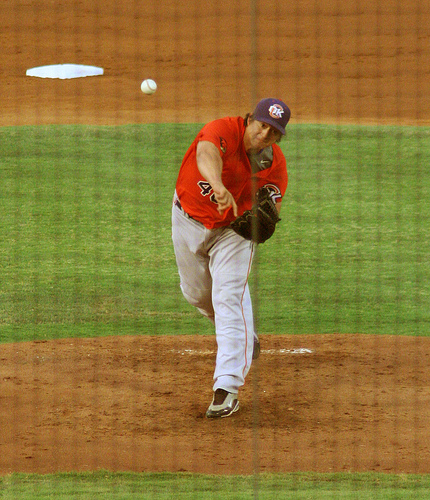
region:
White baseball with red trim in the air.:
[133, 70, 163, 101]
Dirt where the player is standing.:
[1, 340, 428, 474]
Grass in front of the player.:
[3, 471, 426, 498]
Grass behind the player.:
[1, 127, 429, 329]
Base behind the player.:
[25, 60, 106, 84]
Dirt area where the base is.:
[2, 1, 427, 120]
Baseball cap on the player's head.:
[249, 94, 296, 137]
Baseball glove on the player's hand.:
[230, 184, 283, 246]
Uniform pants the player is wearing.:
[162, 202, 270, 398]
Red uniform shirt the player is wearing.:
[163, 103, 306, 232]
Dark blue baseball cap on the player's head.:
[261, 89, 292, 128]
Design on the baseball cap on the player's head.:
[265, 99, 285, 118]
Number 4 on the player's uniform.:
[194, 176, 214, 194]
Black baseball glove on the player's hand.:
[236, 186, 283, 249]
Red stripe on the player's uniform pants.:
[243, 237, 253, 385]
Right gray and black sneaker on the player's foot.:
[206, 375, 242, 419]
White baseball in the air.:
[132, 73, 162, 96]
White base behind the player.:
[23, 46, 110, 85]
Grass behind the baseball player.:
[2, 125, 428, 329]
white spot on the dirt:
[268, 391, 306, 416]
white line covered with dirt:
[122, 331, 210, 362]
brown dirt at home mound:
[26, 311, 194, 452]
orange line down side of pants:
[226, 290, 272, 400]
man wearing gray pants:
[116, 190, 289, 418]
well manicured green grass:
[10, 157, 116, 289]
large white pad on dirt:
[6, 46, 113, 108]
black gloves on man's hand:
[204, 187, 296, 258]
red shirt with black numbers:
[146, 127, 313, 238]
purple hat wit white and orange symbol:
[171, 72, 333, 171]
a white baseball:
[112, 68, 176, 110]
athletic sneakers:
[190, 379, 277, 441]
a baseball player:
[126, 60, 323, 325]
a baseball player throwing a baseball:
[120, 52, 342, 308]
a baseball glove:
[217, 189, 298, 258]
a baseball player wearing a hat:
[163, 55, 341, 266]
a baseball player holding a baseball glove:
[169, 84, 350, 317]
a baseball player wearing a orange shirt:
[170, 71, 319, 282]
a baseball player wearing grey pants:
[164, 64, 313, 489]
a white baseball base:
[22, 45, 149, 142]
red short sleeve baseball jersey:
[171, 110, 294, 249]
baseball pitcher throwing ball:
[155, 100, 298, 437]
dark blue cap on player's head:
[246, 90, 293, 137]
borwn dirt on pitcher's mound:
[33, 351, 150, 459]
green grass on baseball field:
[313, 204, 404, 328]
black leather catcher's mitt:
[231, 189, 281, 249]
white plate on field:
[23, 51, 105, 82]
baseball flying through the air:
[133, 73, 163, 100]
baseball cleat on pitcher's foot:
[202, 380, 243, 419]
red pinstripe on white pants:
[237, 238, 251, 384]